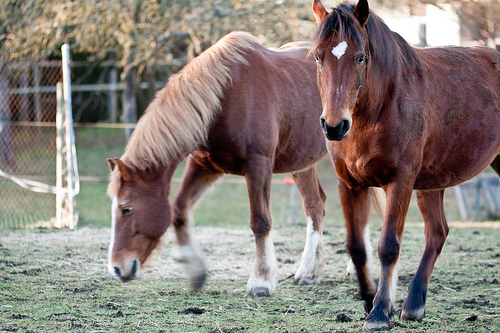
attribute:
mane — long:
[115, 28, 272, 183]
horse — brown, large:
[305, 2, 497, 330]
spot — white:
[327, 39, 356, 60]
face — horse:
[307, 2, 373, 144]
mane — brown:
[304, 2, 420, 68]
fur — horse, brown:
[372, 38, 495, 195]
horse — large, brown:
[104, 28, 333, 301]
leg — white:
[285, 163, 333, 290]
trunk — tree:
[119, 69, 138, 139]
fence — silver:
[10, 43, 148, 233]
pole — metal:
[27, 73, 86, 239]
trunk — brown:
[0, 43, 47, 183]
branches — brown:
[12, 13, 315, 93]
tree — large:
[45, 14, 180, 150]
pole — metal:
[279, 187, 318, 228]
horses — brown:
[61, 58, 480, 301]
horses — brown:
[122, 45, 486, 234]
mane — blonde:
[112, 47, 188, 191]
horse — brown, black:
[307, 45, 457, 297]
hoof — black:
[326, 293, 372, 321]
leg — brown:
[136, 174, 236, 250]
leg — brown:
[286, 181, 380, 267]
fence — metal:
[14, 93, 74, 169]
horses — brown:
[166, 51, 439, 297]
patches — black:
[309, 222, 427, 312]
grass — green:
[177, 291, 237, 329]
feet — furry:
[234, 242, 314, 320]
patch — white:
[318, 7, 356, 76]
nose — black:
[303, 104, 392, 155]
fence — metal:
[27, 57, 111, 236]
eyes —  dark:
[351, 52, 370, 69]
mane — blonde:
[137, 99, 214, 167]